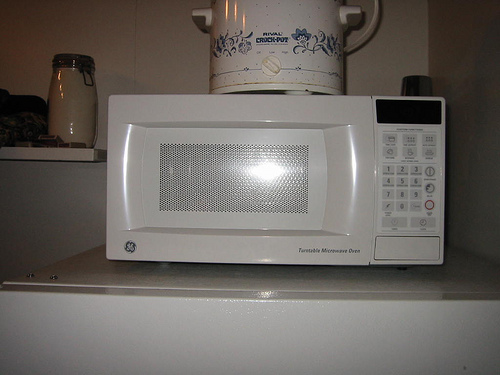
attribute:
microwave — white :
[103, 92, 447, 268]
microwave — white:
[101, 83, 461, 274]